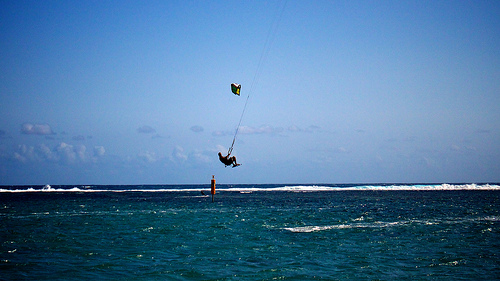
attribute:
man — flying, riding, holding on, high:
[211, 148, 262, 172]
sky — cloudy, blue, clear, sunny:
[71, 14, 146, 74]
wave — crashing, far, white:
[38, 181, 63, 188]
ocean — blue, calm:
[99, 213, 155, 251]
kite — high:
[227, 68, 249, 104]